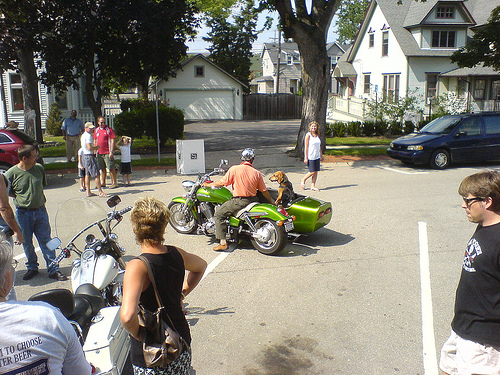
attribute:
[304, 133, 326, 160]
tank top — white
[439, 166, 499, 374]
man — blonde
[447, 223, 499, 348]
shirt — black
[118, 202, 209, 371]
woman — blonde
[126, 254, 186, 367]
purse — black, brown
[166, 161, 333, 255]
motorcyle — green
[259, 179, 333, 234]
side car — green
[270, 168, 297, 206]
dog — sitting, brown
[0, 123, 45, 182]
car — parked, red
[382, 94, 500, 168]
van — parked, blue, parallel parked, minivan, dark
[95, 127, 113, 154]
shirt — red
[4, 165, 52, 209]
shirt — dark, green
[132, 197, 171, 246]
hair — short, blonde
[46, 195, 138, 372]
motorcyle — white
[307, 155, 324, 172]
shorts — blue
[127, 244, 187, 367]
top — black, sleeveless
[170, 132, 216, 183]
box — white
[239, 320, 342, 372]
spot — grease spot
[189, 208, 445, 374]
stripes — white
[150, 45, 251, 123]
garage — white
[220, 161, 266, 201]
shirt — orange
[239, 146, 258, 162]
helmet — silver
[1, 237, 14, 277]
hair — gray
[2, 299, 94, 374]
shirt — dark, gray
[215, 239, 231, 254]
shoes — brown